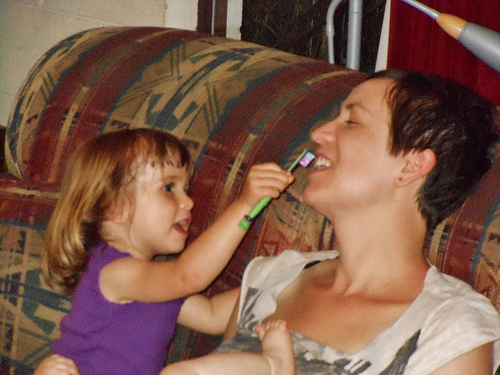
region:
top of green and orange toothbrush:
[290, 143, 319, 176]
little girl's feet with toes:
[250, 316, 302, 358]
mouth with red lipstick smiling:
[307, 151, 340, 187]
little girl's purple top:
[54, 234, 192, 373]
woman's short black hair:
[384, 62, 494, 234]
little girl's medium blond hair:
[36, 115, 188, 266]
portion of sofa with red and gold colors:
[68, 62, 108, 112]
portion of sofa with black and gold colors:
[145, 63, 227, 115]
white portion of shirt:
[426, 281, 475, 346]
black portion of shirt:
[397, 353, 408, 369]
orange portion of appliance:
[426, 5, 473, 40]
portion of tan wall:
[18, 8, 83, 25]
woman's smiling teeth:
[313, 154, 337, 175]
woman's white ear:
[393, 142, 437, 185]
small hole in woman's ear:
[395, 171, 408, 186]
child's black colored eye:
[160, 178, 177, 196]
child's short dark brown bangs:
[137, 115, 199, 172]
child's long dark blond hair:
[29, 126, 126, 293]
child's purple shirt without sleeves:
[68, 246, 207, 370]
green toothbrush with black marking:
[230, 148, 328, 233]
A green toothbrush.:
[233, 137, 317, 233]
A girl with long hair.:
[21, 113, 216, 290]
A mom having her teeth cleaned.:
[261, 55, 478, 284]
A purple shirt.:
[50, 228, 204, 369]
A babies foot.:
[231, 311, 312, 373]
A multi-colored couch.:
[19, 17, 331, 169]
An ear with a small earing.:
[388, 139, 444, 190]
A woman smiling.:
[206, 87, 498, 321]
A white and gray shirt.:
[220, 231, 491, 368]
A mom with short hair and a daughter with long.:
[21, 62, 474, 372]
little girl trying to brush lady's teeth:
[33, 65, 463, 247]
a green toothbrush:
[240, 146, 325, 226]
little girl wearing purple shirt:
[47, 129, 206, 373]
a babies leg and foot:
[141, 314, 301, 374]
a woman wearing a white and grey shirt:
[241, 84, 495, 348]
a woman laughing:
[279, 85, 471, 229]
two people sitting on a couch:
[22, 35, 497, 339]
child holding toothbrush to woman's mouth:
[71, 124, 358, 261]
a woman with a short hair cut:
[298, 55, 486, 231]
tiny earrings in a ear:
[394, 162, 425, 185]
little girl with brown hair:
[35, 123, 293, 373]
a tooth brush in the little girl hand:
[236, 142, 312, 227]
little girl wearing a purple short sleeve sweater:
[47, 242, 188, 374]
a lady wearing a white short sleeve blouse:
[220, 65, 496, 370]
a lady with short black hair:
[361, 67, 495, 223]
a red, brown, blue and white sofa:
[0, 24, 497, 372]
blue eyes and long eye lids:
[162, 175, 194, 197]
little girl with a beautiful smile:
[43, 127, 194, 283]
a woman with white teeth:
[216, 67, 498, 374]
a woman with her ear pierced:
[395, 175, 405, 186]